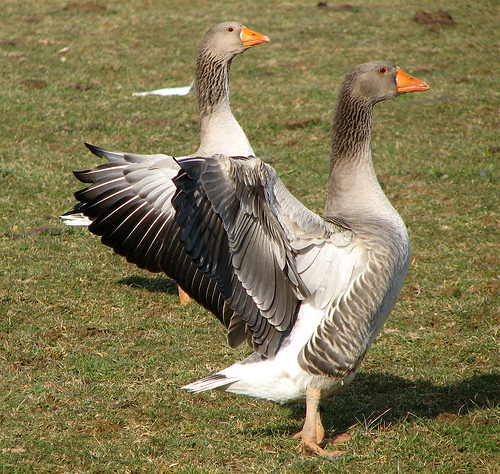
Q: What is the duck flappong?
A: Wings.